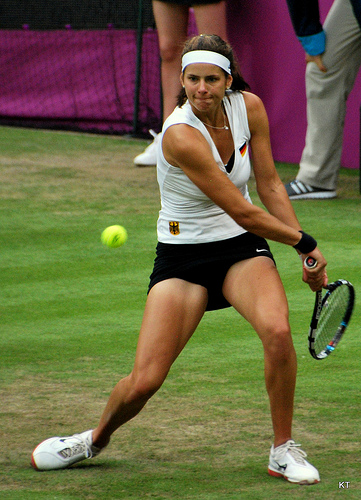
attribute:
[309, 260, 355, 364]
racket — multi-colored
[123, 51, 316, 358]
sportswoman — skilled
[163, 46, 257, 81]
headband — white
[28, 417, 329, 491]
shoes — white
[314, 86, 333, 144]
pants — khaki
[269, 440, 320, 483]
shoe — white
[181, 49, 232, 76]
head band — white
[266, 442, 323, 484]
tennis shoes — white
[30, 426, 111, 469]
tennis shoes — white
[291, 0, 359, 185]
pants — grey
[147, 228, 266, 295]
shorts — dark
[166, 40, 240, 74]
headband — white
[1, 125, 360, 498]
court — green, leveled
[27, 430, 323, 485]
sneakers — white, red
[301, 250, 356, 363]
tennis racquet — black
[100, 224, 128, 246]
tennis ball — yellow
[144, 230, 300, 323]
shorts — black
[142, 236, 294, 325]
shorts — black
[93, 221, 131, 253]
tennis ball — green, bright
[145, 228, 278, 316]
tennis skort — black